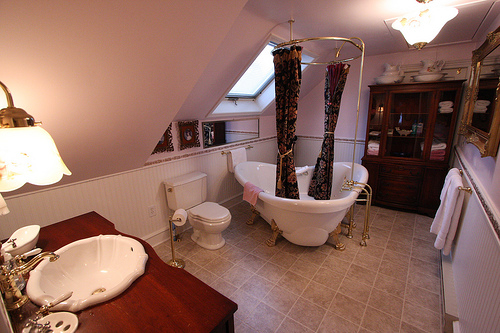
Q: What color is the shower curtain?
A: Brown.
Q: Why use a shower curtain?
A: To keep the room dry.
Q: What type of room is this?
A: A bathroom.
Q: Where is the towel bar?
A: On the right.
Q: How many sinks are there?
A: One sink.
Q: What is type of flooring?
A: Tile flooring.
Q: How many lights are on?
A: Two lights.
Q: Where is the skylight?
A: On the left wall.